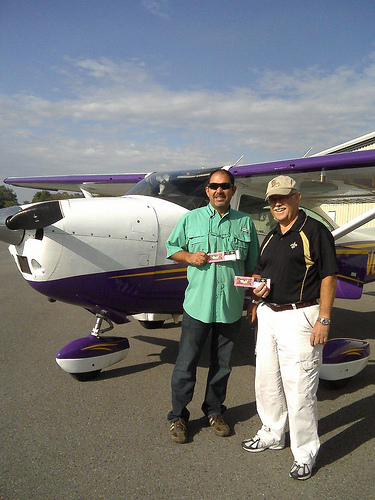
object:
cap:
[264, 175, 299, 202]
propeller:
[5, 200, 66, 241]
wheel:
[69, 368, 102, 382]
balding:
[209, 169, 235, 183]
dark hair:
[208, 168, 234, 185]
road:
[0, 384, 214, 500]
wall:
[177, 57, 216, 90]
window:
[122, 166, 224, 212]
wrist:
[184, 251, 194, 266]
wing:
[229, 149, 375, 207]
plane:
[0, 131, 375, 391]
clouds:
[0, 49, 375, 183]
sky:
[0, 0, 373, 174]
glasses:
[208, 216, 231, 238]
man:
[164, 168, 260, 445]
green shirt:
[164, 201, 259, 324]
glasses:
[207, 182, 233, 189]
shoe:
[208, 416, 230, 437]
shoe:
[168, 417, 188, 444]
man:
[241, 174, 337, 481]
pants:
[254, 300, 325, 465]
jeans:
[167, 308, 242, 422]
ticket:
[233, 275, 271, 289]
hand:
[253, 282, 271, 299]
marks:
[81, 343, 118, 351]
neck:
[209, 201, 229, 219]